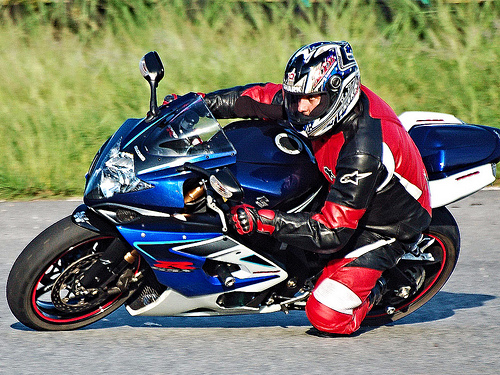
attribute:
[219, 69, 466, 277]
jacket — red ,  man's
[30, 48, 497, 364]
motorcycle —  man's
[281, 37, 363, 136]
helmet — man's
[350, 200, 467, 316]
wheel —  the back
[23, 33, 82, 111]
grass — green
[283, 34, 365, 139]
helmet — white, black, patterned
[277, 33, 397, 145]
head — man's